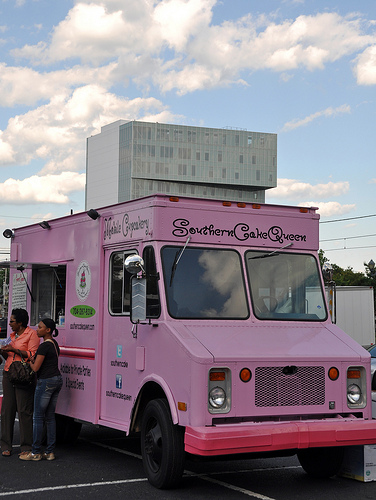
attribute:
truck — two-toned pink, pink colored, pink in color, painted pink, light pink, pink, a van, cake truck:
[5, 192, 372, 485]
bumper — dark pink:
[182, 419, 375, 458]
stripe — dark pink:
[56, 345, 96, 359]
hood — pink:
[167, 322, 372, 363]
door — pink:
[100, 244, 139, 426]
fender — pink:
[155, 320, 192, 429]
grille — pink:
[253, 366, 326, 407]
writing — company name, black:
[170, 215, 309, 245]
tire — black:
[134, 397, 183, 488]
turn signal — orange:
[238, 368, 253, 382]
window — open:
[31, 264, 66, 325]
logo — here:
[74, 258, 93, 303]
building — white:
[251, 285, 375, 348]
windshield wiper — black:
[247, 244, 292, 260]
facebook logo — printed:
[112, 374, 124, 391]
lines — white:
[0, 436, 302, 498]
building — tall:
[84, 119, 278, 210]